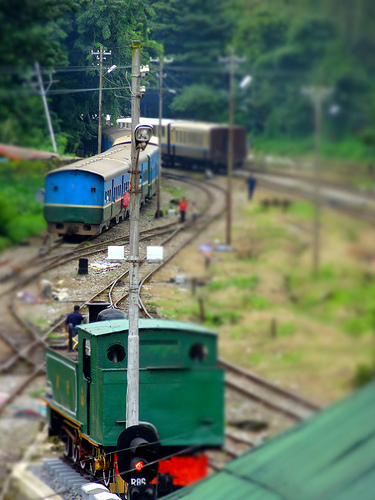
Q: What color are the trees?
A: Green.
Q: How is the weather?
A: Overcast.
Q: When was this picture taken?
A: Daytime.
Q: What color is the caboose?
A: Green.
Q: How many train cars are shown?
A: Three.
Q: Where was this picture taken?
A: A railway.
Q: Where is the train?
A: The train tracks.